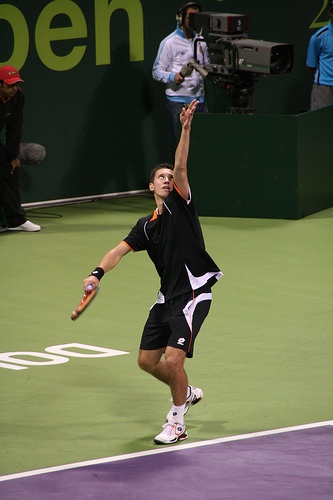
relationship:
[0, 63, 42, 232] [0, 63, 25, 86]
man wearing cap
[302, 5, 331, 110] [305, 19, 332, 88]
man wearing shirt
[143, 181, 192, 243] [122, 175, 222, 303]
lines along top of shirt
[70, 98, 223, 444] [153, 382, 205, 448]
man wearing shoes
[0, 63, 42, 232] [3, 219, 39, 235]
man wearing shoes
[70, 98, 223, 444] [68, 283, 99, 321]
man holding tennis racket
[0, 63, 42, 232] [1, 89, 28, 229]
man wearing black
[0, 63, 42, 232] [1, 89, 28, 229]
man in all black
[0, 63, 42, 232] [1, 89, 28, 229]
man dressed in black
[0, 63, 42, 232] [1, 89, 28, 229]
man clothed in black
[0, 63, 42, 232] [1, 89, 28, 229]
man covered with black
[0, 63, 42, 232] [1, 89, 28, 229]
man dressed in all black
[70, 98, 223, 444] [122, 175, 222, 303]
man wearing shirt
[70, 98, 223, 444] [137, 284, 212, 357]
man wearing shorts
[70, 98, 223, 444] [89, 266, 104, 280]
man wearing wristband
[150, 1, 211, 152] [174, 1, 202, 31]
man wearing headphones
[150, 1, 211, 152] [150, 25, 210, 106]
man wearing jacket